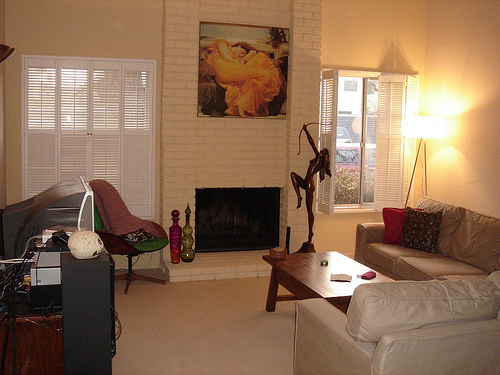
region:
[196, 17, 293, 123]
large painting of woman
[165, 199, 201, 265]
glass decorative bottles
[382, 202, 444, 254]
two pillows on couch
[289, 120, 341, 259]
bronze statue on end table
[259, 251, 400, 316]
brown wooden coffee table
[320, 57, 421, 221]
window with open shutters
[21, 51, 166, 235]
window with closed shutters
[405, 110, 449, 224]
floor lamp in corner is on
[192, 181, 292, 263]
fireplace with no fire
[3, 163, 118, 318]
tv and electronics on shelf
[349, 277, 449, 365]
the sofa is white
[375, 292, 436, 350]
the sofa is white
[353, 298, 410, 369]
the sofa is white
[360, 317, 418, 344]
the sofa is white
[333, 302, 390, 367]
the sofa is white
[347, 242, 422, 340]
the sofa is white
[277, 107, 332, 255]
bronze woman statue with bow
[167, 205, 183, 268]
long slender pink jar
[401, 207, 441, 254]
brown pattern pillow on sofa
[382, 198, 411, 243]
red pillow on sofa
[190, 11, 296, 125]
picture with woman above fireplace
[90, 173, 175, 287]
green chair with blanket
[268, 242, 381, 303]
medium size wooden coffee table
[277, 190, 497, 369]
beige leather sofa set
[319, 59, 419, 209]
window with shutters open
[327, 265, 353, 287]
piece of paper on coffee table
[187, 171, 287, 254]
Fireplace opening in the living room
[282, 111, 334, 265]
Decorative sculpture sitting beside the fireplace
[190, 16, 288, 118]
Picture hung above the fireplace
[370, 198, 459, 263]
Throw pillows sitting on the couch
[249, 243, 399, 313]
Wooden coffee table in the living room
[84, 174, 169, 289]
Chair that seats one person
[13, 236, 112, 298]
Musical system for living room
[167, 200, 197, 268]
Decorative containers sitting on fireplace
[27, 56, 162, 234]
Shutters for large window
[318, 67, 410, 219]
Opened shutters on large window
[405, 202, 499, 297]
the pillow is black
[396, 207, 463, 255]
the pillow is black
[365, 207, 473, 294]
the pillow is black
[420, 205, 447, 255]
the pillow is black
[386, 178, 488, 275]
the pillow is black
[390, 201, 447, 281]
the pillow is black